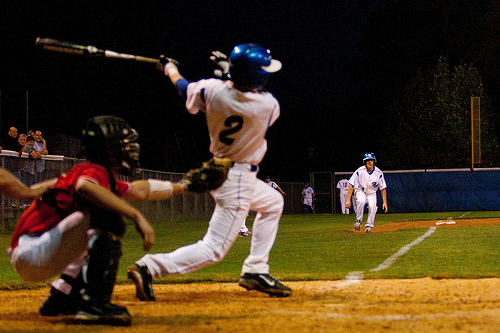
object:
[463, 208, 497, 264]
grass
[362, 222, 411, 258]
stripes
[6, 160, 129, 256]
jersey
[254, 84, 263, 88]
blue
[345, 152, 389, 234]
man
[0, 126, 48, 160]
spectator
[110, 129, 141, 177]
mask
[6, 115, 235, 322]
child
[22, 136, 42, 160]
person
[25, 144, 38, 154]
green shirt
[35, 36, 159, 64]
bat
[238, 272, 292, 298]
nike cleat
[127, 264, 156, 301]
nike cleat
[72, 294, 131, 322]
nike cleat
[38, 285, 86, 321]
nike cleat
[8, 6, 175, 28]
sky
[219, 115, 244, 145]
blue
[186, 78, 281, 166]
jersey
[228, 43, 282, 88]
helmet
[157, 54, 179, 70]
glove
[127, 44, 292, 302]
baseball player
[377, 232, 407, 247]
grass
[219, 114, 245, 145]
number